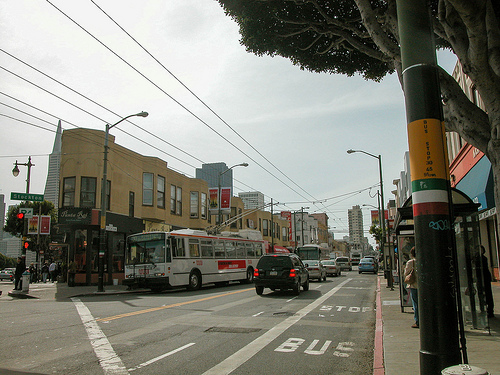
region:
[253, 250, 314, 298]
SUV on the road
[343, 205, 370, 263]
tall building in the distance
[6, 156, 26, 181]
light on the street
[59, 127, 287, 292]
building on corner of street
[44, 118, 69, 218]
building with pointed structure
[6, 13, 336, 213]
wires carrying power supply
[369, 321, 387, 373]
curb of the sidewalk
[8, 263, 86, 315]
corner of the street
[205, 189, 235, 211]
banners on side of building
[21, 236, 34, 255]
pedestrian walk light lit up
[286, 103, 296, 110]
part of a cloud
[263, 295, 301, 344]
part of a line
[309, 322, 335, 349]
part of a numner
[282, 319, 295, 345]
part of a letter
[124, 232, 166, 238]
The marquee display on the bus.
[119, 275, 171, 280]
The headlights of the bus.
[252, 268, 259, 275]
The left brake light on the SUV.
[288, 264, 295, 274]
The right brake light on the SUV.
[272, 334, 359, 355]
The word BUS on the street.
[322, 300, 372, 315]
The word STOP on the bus.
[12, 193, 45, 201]
The green street sign.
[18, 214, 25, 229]
The red traffic light under the street sign.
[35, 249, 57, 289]
The people on the sidewalk on the left.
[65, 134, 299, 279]
The beige business buildings on the left.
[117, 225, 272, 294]
bus on a street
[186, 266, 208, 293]
front wheel on a bus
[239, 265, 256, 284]
rear wheel on a bus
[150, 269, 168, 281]
front headlight on a bus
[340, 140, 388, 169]
streetlight on a pole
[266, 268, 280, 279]
rear licence plate on a vehicle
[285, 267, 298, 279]
rear tail light on a vehicle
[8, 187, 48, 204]
street sign on a pole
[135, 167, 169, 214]
windows on a building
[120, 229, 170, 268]
front windshield on a bus